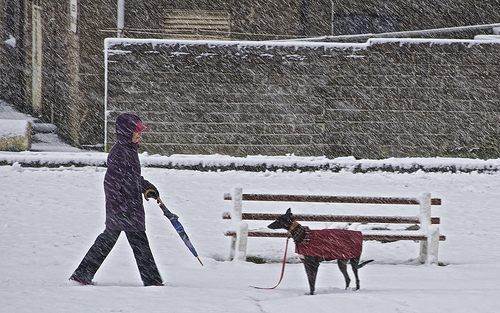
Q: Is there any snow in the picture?
A: Yes, there is snow.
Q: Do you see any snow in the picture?
A: Yes, there is snow.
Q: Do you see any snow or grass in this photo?
A: Yes, there is snow.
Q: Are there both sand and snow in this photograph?
A: No, there is snow but no sand.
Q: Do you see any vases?
A: No, there are no vases.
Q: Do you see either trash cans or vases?
A: No, there are no vases or trash cans.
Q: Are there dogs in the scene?
A: Yes, there is a dog.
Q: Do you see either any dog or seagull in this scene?
A: Yes, there is a dog.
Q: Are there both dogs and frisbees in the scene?
A: No, there is a dog but no frisbees.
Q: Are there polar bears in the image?
A: No, there are no polar bears.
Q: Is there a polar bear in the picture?
A: No, there are no polar bears.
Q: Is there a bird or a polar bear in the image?
A: No, there are no polar bears or birds.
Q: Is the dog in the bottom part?
A: Yes, the dog is in the bottom of the image.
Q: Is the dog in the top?
A: No, the dog is in the bottom of the image.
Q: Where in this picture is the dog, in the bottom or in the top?
A: The dog is in the bottom of the image.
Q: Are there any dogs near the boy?
A: Yes, there is a dog near the boy.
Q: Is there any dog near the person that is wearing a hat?
A: Yes, there is a dog near the boy.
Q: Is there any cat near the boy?
A: No, there is a dog near the boy.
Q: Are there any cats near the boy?
A: No, there is a dog near the boy.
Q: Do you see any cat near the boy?
A: No, there is a dog near the boy.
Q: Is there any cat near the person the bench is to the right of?
A: No, there is a dog near the boy.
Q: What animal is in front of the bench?
A: The dog is in front of the bench.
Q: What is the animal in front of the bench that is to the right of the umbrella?
A: The animal is a dog.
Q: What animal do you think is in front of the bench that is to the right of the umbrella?
A: The animal is a dog.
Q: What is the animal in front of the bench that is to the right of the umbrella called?
A: The animal is a dog.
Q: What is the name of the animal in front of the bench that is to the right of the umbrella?
A: The animal is a dog.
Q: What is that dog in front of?
A: The dog is in front of the bench.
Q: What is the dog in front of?
A: The dog is in front of the bench.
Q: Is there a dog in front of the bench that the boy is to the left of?
A: Yes, there is a dog in front of the bench.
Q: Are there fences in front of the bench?
A: No, there is a dog in front of the bench.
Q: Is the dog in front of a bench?
A: Yes, the dog is in front of a bench.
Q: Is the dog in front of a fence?
A: No, the dog is in front of a bench.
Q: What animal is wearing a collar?
A: The dog is wearing a collar.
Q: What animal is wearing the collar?
A: The animal is a dog.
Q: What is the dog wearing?
A: The dog is wearing a collar.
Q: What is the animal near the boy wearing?
A: The dog is wearing a collar.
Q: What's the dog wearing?
A: The dog is wearing a collar.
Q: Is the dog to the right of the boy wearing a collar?
A: Yes, the dog is wearing a collar.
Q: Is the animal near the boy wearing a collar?
A: Yes, the dog is wearing a collar.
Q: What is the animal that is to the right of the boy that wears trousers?
A: The animal is a dog.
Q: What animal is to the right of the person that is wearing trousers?
A: The animal is a dog.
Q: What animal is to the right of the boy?
A: The animal is a dog.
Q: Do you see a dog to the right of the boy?
A: Yes, there is a dog to the right of the boy.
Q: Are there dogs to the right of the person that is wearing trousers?
A: Yes, there is a dog to the right of the boy.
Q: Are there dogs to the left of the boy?
A: No, the dog is to the right of the boy.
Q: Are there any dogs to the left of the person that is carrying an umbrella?
A: No, the dog is to the right of the boy.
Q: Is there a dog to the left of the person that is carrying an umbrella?
A: No, the dog is to the right of the boy.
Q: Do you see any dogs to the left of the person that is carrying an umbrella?
A: No, the dog is to the right of the boy.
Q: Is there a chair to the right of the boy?
A: No, there is a dog to the right of the boy.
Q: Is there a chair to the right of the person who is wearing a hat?
A: No, there is a dog to the right of the boy.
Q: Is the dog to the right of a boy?
A: Yes, the dog is to the right of a boy.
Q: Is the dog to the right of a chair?
A: No, the dog is to the right of a boy.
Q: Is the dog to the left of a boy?
A: No, the dog is to the right of a boy.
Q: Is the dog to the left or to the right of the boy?
A: The dog is to the right of the boy.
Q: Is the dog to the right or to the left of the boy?
A: The dog is to the right of the boy.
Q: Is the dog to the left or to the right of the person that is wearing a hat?
A: The dog is to the right of the boy.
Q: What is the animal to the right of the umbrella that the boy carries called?
A: The animal is a dog.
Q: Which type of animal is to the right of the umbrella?
A: The animal is a dog.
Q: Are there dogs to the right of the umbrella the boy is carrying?
A: Yes, there is a dog to the right of the umbrella.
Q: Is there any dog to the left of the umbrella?
A: No, the dog is to the right of the umbrella.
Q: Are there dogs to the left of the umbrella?
A: No, the dog is to the right of the umbrella.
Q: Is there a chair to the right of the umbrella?
A: No, there is a dog to the right of the umbrella.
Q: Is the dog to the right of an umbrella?
A: Yes, the dog is to the right of an umbrella.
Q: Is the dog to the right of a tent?
A: No, the dog is to the right of an umbrella.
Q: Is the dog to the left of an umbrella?
A: No, the dog is to the right of an umbrella.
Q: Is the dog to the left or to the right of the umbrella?
A: The dog is to the right of the umbrella.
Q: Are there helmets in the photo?
A: No, there are no helmets.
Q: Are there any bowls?
A: No, there are no bowls.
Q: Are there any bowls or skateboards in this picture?
A: No, there are no bowls or skateboards.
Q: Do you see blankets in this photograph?
A: Yes, there is a blanket.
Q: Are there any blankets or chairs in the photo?
A: Yes, there is a blanket.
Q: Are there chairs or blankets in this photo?
A: Yes, there is a blanket.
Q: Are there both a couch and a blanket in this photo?
A: No, there is a blanket but no couches.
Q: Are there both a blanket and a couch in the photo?
A: No, there is a blanket but no couches.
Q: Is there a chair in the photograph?
A: No, there are no chairs.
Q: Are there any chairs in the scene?
A: No, there are no chairs.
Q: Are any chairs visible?
A: No, there are no chairs.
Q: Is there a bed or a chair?
A: No, there are no chairs or beds.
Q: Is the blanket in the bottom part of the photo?
A: Yes, the blanket is in the bottom of the image.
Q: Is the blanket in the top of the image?
A: No, the blanket is in the bottom of the image.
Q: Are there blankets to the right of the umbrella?
A: Yes, there is a blanket to the right of the umbrella.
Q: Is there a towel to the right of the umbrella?
A: No, there is a blanket to the right of the umbrella.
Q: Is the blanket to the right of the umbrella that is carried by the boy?
A: Yes, the blanket is to the right of the umbrella.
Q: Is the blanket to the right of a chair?
A: No, the blanket is to the right of the umbrella.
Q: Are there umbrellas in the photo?
A: Yes, there is an umbrella.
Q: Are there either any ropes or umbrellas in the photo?
A: Yes, there is an umbrella.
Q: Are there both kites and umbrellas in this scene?
A: No, there is an umbrella but no kites.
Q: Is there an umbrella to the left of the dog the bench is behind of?
A: Yes, there is an umbrella to the left of the dog.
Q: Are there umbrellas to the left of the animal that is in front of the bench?
A: Yes, there is an umbrella to the left of the dog.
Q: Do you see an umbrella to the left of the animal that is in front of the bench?
A: Yes, there is an umbrella to the left of the dog.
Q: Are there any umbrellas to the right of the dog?
A: No, the umbrella is to the left of the dog.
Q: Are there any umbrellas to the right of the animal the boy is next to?
A: No, the umbrella is to the left of the dog.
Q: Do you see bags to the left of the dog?
A: No, there is an umbrella to the left of the dog.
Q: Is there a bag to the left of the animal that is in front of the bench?
A: No, there is an umbrella to the left of the dog.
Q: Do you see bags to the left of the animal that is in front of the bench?
A: No, there is an umbrella to the left of the dog.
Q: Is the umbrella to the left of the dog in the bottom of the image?
A: Yes, the umbrella is to the left of the dog.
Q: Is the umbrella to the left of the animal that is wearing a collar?
A: Yes, the umbrella is to the left of the dog.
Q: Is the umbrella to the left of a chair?
A: No, the umbrella is to the left of the dog.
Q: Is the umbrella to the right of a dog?
A: No, the umbrella is to the left of a dog.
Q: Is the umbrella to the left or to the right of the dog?
A: The umbrella is to the left of the dog.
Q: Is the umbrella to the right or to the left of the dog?
A: The umbrella is to the left of the dog.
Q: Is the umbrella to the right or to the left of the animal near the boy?
A: The umbrella is to the left of the dog.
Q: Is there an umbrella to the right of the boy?
A: Yes, there is an umbrella to the right of the boy.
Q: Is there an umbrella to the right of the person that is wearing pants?
A: Yes, there is an umbrella to the right of the boy.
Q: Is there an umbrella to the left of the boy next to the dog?
A: No, the umbrella is to the right of the boy.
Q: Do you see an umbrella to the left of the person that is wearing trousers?
A: No, the umbrella is to the right of the boy.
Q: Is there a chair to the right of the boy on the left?
A: No, there is an umbrella to the right of the boy.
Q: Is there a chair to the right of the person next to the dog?
A: No, there is an umbrella to the right of the boy.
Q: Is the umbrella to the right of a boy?
A: Yes, the umbrella is to the right of a boy.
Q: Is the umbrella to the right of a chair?
A: No, the umbrella is to the right of a boy.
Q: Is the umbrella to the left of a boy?
A: No, the umbrella is to the right of a boy.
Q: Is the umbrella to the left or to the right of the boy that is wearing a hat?
A: The umbrella is to the right of the boy.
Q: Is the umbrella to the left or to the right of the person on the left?
A: The umbrella is to the right of the boy.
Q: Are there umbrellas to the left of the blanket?
A: Yes, there is an umbrella to the left of the blanket.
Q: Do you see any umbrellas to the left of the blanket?
A: Yes, there is an umbrella to the left of the blanket.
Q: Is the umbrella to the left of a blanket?
A: Yes, the umbrella is to the left of a blanket.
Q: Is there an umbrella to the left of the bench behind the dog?
A: Yes, there is an umbrella to the left of the bench.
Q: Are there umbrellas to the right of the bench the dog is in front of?
A: No, the umbrella is to the left of the bench.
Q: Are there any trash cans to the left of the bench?
A: No, there is an umbrella to the left of the bench.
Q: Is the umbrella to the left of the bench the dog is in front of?
A: Yes, the umbrella is to the left of the bench.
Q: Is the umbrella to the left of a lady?
A: No, the umbrella is to the left of the bench.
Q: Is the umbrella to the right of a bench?
A: No, the umbrella is to the left of a bench.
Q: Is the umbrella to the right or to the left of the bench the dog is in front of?
A: The umbrella is to the left of the bench.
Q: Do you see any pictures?
A: No, there are no pictures.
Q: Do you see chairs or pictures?
A: No, there are no pictures or chairs.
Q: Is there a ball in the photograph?
A: No, there are no balls.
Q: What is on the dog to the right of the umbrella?
A: The outfit is on the dog.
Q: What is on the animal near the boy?
A: The outfit is on the dog.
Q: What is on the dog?
A: The outfit is on the dog.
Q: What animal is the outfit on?
A: The outfit is on the dog.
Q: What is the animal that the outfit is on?
A: The animal is a dog.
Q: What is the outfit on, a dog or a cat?
A: The outfit is on a dog.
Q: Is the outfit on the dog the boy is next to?
A: Yes, the outfit is on the dog.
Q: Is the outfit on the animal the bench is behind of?
A: Yes, the outfit is on the dog.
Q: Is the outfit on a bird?
A: No, the outfit is on the dog.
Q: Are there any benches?
A: Yes, there is a bench.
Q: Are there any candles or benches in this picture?
A: Yes, there is a bench.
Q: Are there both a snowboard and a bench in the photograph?
A: No, there is a bench but no snowboards.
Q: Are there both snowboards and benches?
A: No, there is a bench but no snowboards.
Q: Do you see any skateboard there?
A: No, there are no skateboards.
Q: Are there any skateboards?
A: No, there are no skateboards.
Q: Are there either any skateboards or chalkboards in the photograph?
A: No, there are no skateboards or chalkboards.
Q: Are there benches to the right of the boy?
A: Yes, there is a bench to the right of the boy.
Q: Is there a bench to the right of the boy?
A: Yes, there is a bench to the right of the boy.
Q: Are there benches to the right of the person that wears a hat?
A: Yes, there is a bench to the right of the boy.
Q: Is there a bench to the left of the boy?
A: No, the bench is to the right of the boy.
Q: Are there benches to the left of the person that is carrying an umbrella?
A: No, the bench is to the right of the boy.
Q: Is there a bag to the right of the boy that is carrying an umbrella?
A: No, there is a bench to the right of the boy.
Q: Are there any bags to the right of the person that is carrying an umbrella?
A: No, there is a bench to the right of the boy.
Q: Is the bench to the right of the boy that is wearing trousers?
A: Yes, the bench is to the right of the boy.